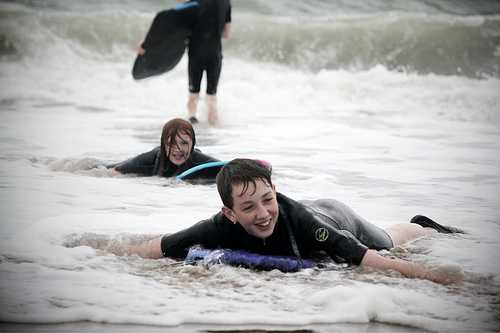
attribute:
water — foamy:
[262, 66, 475, 165]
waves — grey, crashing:
[245, 8, 494, 81]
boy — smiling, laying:
[145, 161, 466, 283]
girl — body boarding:
[107, 117, 195, 179]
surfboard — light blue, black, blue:
[179, 161, 218, 180]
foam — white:
[239, 65, 494, 160]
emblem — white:
[315, 226, 329, 241]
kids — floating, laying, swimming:
[114, 1, 457, 285]